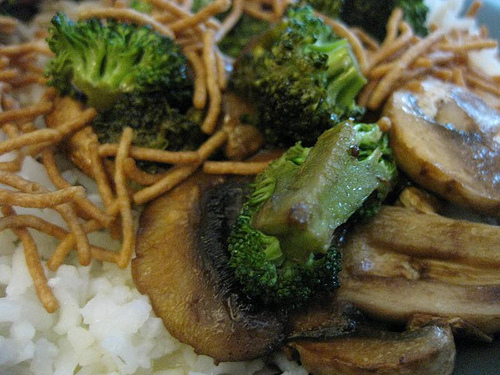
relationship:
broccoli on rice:
[41, 10, 198, 149] [1, 1, 499, 373]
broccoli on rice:
[215, 124, 388, 297] [1, 1, 499, 373]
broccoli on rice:
[226, 19, 368, 146] [1, 1, 499, 373]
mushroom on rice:
[384, 85, 499, 216] [1, 1, 499, 373]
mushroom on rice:
[127, 163, 496, 368] [1, 1, 499, 373]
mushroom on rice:
[277, 309, 467, 375] [1, 1, 499, 373]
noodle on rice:
[1, 203, 62, 317] [1, 1, 499, 373]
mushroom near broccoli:
[384, 85, 499, 216] [39, 5, 395, 287]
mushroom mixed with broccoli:
[127, 163, 496, 368] [41, 10, 198, 149]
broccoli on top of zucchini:
[215, 124, 388, 297] [127, 179, 344, 367]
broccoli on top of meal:
[215, 124, 388, 297] [1, 0, 498, 373]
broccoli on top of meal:
[226, 19, 368, 146] [1, 0, 498, 373]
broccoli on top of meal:
[41, 10, 198, 149] [1, 0, 498, 373]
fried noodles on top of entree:
[18, 61, 191, 271] [1, 2, 499, 373]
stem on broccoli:
[326, 32, 368, 89] [226, 19, 368, 146]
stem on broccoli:
[73, 75, 122, 115] [47, 10, 197, 182]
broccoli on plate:
[41, 10, 198, 149] [0, 0, 499, 373]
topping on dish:
[0, 1, 499, 313] [16, 15, 498, 357]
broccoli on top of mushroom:
[41, 10, 198, 149] [127, 163, 496, 368]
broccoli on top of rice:
[41, 10, 198, 149] [2, 146, 288, 373]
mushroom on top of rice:
[127, 163, 496, 368] [2, 146, 288, 373]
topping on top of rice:
[10, 101, 154, 290] [13, 259, 172, 371]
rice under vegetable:
[7, 177, 144, 367] [66, 24, 418, 286]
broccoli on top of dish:
[41, 10, 198, 149] [1, 0, 499, 373]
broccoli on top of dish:
[226, 19, 368, 146] [1, 0, 499, 373]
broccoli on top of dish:
[215, 124, 388, 297] [1, 0, 499, 373]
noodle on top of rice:
[1, 203, 62, 317] [42, 256, 179, 350]